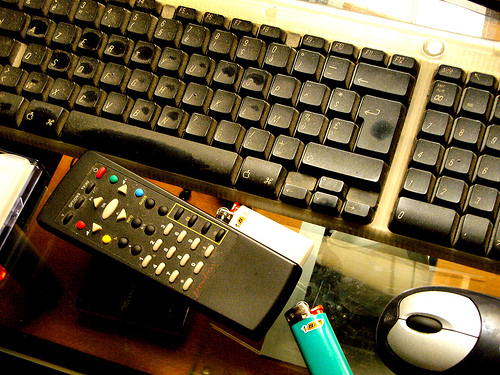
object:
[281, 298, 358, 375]
lighter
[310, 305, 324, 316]
button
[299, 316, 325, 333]
logo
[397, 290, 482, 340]
button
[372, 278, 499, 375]
mouse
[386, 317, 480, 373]
button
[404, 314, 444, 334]
wheel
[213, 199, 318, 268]
lighter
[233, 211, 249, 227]
logo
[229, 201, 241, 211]
button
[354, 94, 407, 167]
key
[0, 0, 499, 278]
keyboard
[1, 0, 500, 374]
desk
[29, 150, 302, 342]
remote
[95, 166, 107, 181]
button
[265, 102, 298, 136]
key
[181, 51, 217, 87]
key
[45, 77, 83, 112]
key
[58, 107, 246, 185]
spacebar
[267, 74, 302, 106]
key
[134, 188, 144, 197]
button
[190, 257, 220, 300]
print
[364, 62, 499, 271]
pad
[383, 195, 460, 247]
button